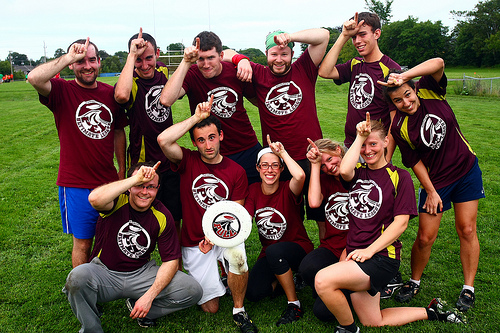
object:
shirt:
[249, 48, 322, 161]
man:
[28, 36, 130, 293]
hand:
[136, 161, 161, 183]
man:
[318, 12, 402, 164]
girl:
[314, 111, 467, 332]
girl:
[298, 138, 350, 323]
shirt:
[38, 78, 130, 189]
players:
[21, 17, 498, 327]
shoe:
[231, 311, 259, 332]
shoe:
[428, 298, 468, 327]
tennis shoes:
[394, 281, 420, 303]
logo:
[192, 173, 230, 210]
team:
[29, 12, 484, 331]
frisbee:
[202, 201, 253, 248]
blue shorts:
[58, 186, 99, 240]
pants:
[65, 257, 203, 333]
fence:
[447, 72, 499, 94]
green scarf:
[265, 31, 293, 50]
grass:
[1, 69, 497, 332]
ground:
[2, 68, 494, 332]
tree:
[453, 0, 499, 69]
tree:
[379, 15, 449, 68]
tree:
[239, 48, 267, 66]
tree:
[6, 51, 30, 65]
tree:
[364, 0, 394, 26]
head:
[189, 114, 224, 159]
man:
[222, 28, 331, 240]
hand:
[69, 36, 90, 61]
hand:
[274, 33, 292, 50]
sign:
[304, 137, 324, 160]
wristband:
[232, 54, 250, 69]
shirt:
[390, 71, 476, 189]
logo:
[420, 113, 446, 149]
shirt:
[170, 146, 250, 247]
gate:
[462, 73, 498, 95]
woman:
[249, 147, 296, 286]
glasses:
[258, 162, 283, 170]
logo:
[75, 100, 113, 140]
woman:
[366, 90, 493, 287]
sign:
[424, 101, 453, 167]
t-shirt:
[178, 60, 258, 156]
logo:
[207, 86, 239, 118]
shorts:
[355, 254, 401, 297]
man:
[114, 27, 181, 237]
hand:
[130, 27, 149, 56]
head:
[128, 33, 160, 78]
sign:
[351, 12, 362, 32]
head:
[349, 11, 382, 55]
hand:
[342, 12, 365, 36]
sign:
[150, 158, 161, 174]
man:
[65, 161, 203, 333]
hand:
[266, 134, 284, 156]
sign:
[261, 127, 272, 146]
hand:
[377, 73, 405, 88]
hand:
[198, 238, 214, 254]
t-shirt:
[86, 191, 182, 272]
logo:
[117, 220, 152, 260]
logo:
[264, 81, 302, 116]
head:
[265, 30, 295, 74]